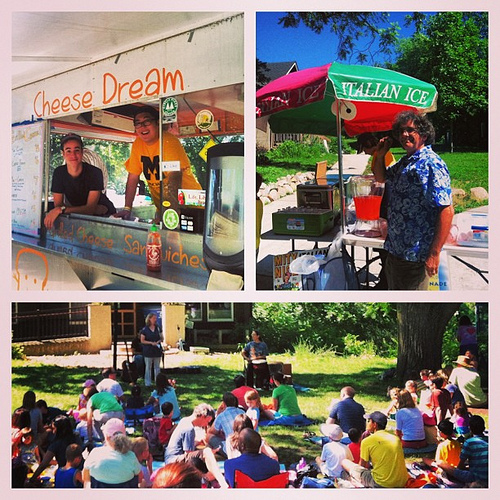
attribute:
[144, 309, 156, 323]
hat — tan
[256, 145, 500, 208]
grass — green, manicured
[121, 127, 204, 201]
shirt — orange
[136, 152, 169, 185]
word — black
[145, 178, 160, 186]
word — black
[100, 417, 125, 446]
hat — pink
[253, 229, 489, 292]
pavement — stone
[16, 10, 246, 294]
truck — food truck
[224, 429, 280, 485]
man — sitting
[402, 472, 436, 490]
pillow — red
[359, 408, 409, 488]
man — sitting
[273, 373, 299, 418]
woman — sitting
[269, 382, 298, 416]
shirt — green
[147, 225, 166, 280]
bottle — red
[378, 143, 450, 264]
shirt — hawaiian, blue, white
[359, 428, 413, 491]
t-shirt — yellow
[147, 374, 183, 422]
person — sitting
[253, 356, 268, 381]
drum — bongo drum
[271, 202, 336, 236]
cooler — green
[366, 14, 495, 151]
tree — large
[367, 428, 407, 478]
shirt — yellow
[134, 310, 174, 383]
woman — speaking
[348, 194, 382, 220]
italian ice — red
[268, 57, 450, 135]
umbrella — Italian ice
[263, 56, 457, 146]
umbrella — red, green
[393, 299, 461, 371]
tree trunk — large, brown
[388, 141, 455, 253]
shirt — blue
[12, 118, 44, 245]
board — dry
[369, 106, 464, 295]
man — old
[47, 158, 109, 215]
shirt — black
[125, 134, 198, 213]
shirt — yellow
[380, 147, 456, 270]
shirt — blue, white, floral